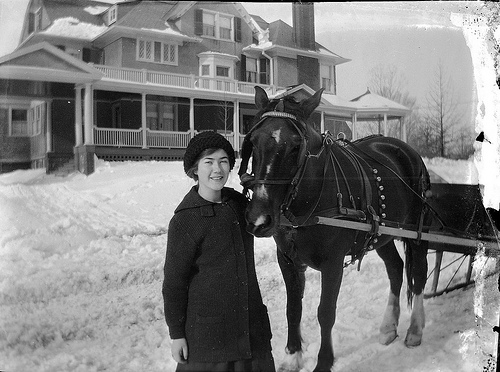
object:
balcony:
[96, 43, 273, 97]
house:
[0, 0, 414, 177]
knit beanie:
[183, 131, 235, 172]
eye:
[290, 145, 299, 153]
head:
[197, 147, 231, 189]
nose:
[214, 162, 222, 172]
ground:
[0, 187, 499, 372]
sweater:
[163, 184, 270, 359]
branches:
[430, 93, 441, 106]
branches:
[424, 132, 429, 146]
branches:
[379, 68, 390, 96]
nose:
[245, 214, 275, 237]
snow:
[39, 17, 108, 39]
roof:
[15, 32, 88, 50]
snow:
[0, 163, 183, 371]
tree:
[427, 60, 459, 157]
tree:
[365, 65, 406, 135]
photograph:
[0, 0, 498, 369]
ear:
[302, 88, 325, 115]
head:
[246, 86, 325, 237]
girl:
[161, 130, 276, 371]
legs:
[276, 249, 304, 352]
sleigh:
[318, 138, 498, 249]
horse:
[240, 86, 434, 371]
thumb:
[183, 348, 188, 359]